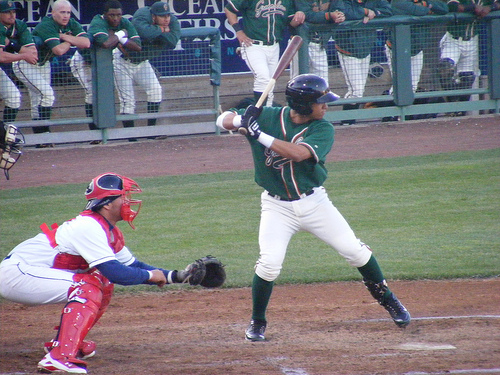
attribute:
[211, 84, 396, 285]
uniform — green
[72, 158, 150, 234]
helmet — red, blue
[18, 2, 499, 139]
players — waiting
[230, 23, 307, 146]
bat — brown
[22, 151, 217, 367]
catcher — waiting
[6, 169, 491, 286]
grass — green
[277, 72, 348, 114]
helmet — black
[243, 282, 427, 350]
cleets — black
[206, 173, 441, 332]
legs — apart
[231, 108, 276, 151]
gloves — black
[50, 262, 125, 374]
shin guards — red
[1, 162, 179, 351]
player — squating, waiting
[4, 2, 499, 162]
fence — grilled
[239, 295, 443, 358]
shoes — black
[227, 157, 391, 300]
pants — white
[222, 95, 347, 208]
jersey — green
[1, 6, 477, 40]
jerseys — green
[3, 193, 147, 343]
outfit — white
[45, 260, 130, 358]
knee pads — red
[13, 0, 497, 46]
railing — padded